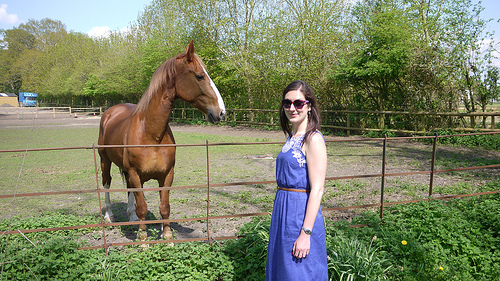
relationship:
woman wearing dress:
[264, 82, 330, 280] [267, 126, 331, 281]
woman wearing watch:
[264, 82, 330, 280] [300, 224, 316, 237]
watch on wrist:
[300, 224, 316, 237] [298, 228, 317, 242]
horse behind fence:
[98, 41, 231, 251] [3, 126, 493, 259]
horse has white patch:
[98, 41, 231, 251] [198, 61, 229, 125]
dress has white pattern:
[267, 126, 331, 281] [292, 135, 306, 171]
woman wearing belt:
[264, 82, 330, 280] [277, 184, 312, 195]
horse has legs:
[98, 41, 231, 251] [99, 154, 177, 249]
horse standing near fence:
[98, 41, 231, 251] [3, 126, 493, 259]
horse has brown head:
[98, 41, 231, 251] [172, 42, 228, 125]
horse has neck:
[98, 41, 231, 251] [138, 58, 182, 141]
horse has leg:
[98, 41, 231, 251] [99, 155, 118, 226]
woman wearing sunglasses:
[264, 82, 330, 280] [281, 99, 312, 109]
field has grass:
[3, 118, 499, 251] [11, 130, 34, 141]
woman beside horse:
[264, 82, 330, 280] [98, 41, 231, 251]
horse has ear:
[98, 41, 231, 251] [187, 38, 196, 65]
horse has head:
[98, 41, 231, 251] [172, 42, 228, 125]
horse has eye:
[98, 41, 231, 251] [192, 72, 206, 82]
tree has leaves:
[348, 7, 417, 138] [367, 60, 397, 76]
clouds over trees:
[84, 21, 142, 42] [28, 14, 145, 110]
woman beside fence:
[264, 82, 330, 280] [3, 126, 493, 259]